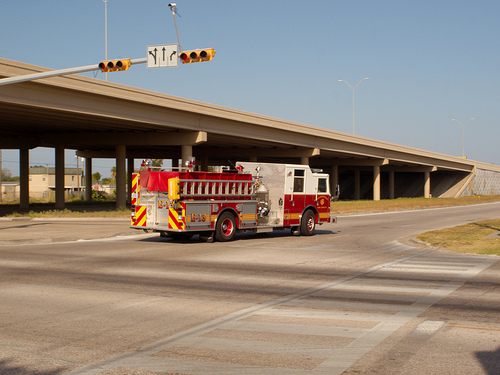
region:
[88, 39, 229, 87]
two horizontal traffic lights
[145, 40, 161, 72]
sign for going forward and turning left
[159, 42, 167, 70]
sign for going forward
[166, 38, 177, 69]
sign for turning right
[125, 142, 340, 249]
red and white firetruck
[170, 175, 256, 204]
detachable ladder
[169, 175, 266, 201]
ladder on the side of firetruck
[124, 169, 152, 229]
red and yellow pattern to attract attention to truck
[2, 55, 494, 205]
large multi-lane bridge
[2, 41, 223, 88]
pole holding two traffic lights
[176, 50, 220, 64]
traffic light signal on pole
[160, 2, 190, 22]
white camera attached to pole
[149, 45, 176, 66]
white road signs on pole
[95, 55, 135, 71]
yellow traffic signal lights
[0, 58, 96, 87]
long gray pole in air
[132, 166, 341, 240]
red fire truck on road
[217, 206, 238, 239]
rear right tire on truck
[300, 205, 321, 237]
right front tire on fire truck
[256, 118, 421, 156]
highway overpass over road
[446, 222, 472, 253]
grass on the ground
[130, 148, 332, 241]
Red and yellow fire truck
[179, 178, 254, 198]
Gray ladder on side of fire truck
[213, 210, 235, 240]
Red rim on wheel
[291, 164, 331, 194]
Windows on side of fire truck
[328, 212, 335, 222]
Chrome bumper on side of fire truck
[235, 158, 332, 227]
White cab on front of fire truck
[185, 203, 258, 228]
Yellow logo on side of fire truck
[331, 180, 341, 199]
Mirror on side of fire truck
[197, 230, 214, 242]
Black mud flap on side of fire truck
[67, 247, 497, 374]
Crosswalk on the road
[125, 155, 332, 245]
a red and white fire truck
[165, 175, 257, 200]
a ladder on a fire truck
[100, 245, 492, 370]
a faded crosswalk on a road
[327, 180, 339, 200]
a sideview mirror on a firetruck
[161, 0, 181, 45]
a camera above a light post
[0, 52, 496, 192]
a bridge going over a road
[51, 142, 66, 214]
a column supporting a bridge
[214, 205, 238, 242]
a wheel on a fire truck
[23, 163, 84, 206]
a building in the distance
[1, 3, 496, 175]
a clear blue sky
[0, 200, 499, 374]
a concrete road and intersection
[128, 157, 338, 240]
a fire truck on the road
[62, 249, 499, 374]
a crosswalk in the intersection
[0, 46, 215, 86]
a traffic light over the intersection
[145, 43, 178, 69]
a sign on the traffic light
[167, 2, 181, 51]
a camera on the traffic light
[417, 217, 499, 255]
a patch of grass at the intersection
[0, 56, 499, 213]
a bridge near the intersection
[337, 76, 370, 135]
a street light on the bridge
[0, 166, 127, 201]
a building in the background